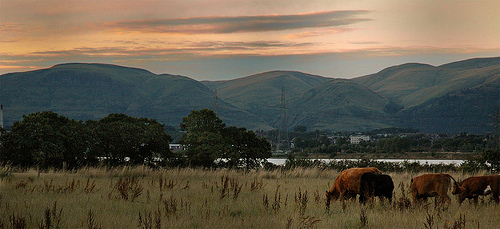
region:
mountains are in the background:
[5, 57, 499, 147]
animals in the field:
[320, 157, 499, 213]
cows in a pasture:
[315, 151, 498, 221]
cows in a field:
[319, 160, 499, 220]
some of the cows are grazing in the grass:
[247, 162, 493, 227]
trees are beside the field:
[15, 103, 498, 173]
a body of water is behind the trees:
[67, 154, 499, 170]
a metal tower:
[275, 77, 295, 156]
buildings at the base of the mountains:
[320, 130, 456, 152]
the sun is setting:
[11, 5, 498, 68]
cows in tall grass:
[320, 161, 490, 218]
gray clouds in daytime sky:
[218, 11, 327, 43]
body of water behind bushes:
[258, 150, 436, 166]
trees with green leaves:
[28, 107, 225, 162]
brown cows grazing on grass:
[322, 169, 494, 213]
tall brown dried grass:
[150, 179, 258, 224]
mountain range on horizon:
[33, 59, 387, 109]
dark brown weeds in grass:
[103, 176, 158, 207]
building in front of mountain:
[337, 124, 389, 154]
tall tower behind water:
[270, 85, 302, 160]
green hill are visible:
[237, 72, 331, 119]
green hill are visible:
[187, 31, 351, 101]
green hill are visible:
[194, 52, 338, 153]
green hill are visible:
[142, 55, 250, 167]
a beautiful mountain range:
[37, 55, 489, 182]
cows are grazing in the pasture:
[331, 155, 499, 217]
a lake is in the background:
[119, 121, 464, 170]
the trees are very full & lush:
[27, 102, 270, 197]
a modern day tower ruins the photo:
[268, 69, 305, 161]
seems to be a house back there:
[345, 122, 372, 144]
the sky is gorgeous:
[82, 24, 373, 72]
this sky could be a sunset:
[33, 21, 499, 62]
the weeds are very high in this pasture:
[123, 174, 299, 216]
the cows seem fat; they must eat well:
[306, 153, 496, 208]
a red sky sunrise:
[1, 0, 498, 58]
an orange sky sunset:
[1, 0, 498, 58]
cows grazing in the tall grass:
[1, 167, 499, 227]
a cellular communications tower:
[275, 72, 290, 157]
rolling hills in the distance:
[0, 53, 499, 131]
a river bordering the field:
[239, 156, 479, 167]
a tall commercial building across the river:
[349, 132, 370, 145]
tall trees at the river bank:
[0, 108, 273, 171]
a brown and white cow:
[451, 175, 498, 207]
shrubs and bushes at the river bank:
[262, 158, 497, 170]